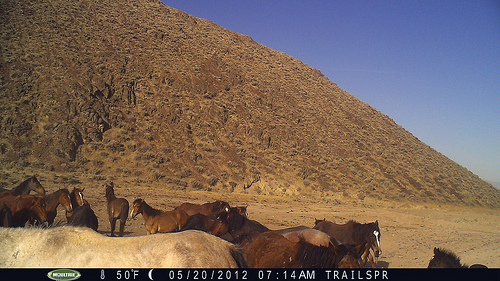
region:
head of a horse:
[362, 215, 400, 262]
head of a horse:
[222, 204, 257, 243]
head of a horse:
[125, 186, 159, 224]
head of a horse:
[100, 176, 127, 203]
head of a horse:
[72, 168, 94, 214]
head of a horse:
[51, 189, 82, 221]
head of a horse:
[30, 180, 53, 195]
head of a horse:
[32, 189, 63, 221]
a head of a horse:
[72, 176, 97, 206]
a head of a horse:
[25, 167, 48, 197]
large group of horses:
[27, 167, 410, 266]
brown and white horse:
[316, 204, 393, 262]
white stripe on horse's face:
[365, 232, 382, 256]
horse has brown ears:
[360, 211, 379, 233]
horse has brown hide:
[316, 211, 377, 253]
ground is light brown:
[322, 204, 447, 274]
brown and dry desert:
[403, 211, 463, 258]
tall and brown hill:
[3, 11, 395, 202]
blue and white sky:
[403, 72, 499, 188]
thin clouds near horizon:
[425, 74, 497, 186]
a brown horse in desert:
[102, 180, 128, 235]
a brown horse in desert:
[66, 185, 89, 222]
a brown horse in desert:
[32, 184, 74, 226]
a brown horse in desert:
[0, 189, 46, 227]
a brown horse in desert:
[9, 174, 45, 196]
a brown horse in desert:
[129, 196, 186, 233]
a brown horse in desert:
[175, 197, 230, 214]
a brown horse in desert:
[183, 205, 248, 234]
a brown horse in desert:
[207, 205, 267, 242]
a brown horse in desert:
[241, 227, 364, 267]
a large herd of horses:
[7, 168, 459, 264]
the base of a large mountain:
[10, 5, 474, 199]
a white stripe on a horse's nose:
[367, 223, 387, 256]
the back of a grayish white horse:
[7, 230, 226, 264]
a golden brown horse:
[122, 200, 192, 230]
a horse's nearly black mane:
[283, 235, 348, 268]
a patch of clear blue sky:
[237, 10, 497, 172]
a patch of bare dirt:
[309, 202, 484, 269]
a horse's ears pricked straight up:
[423, 243, 445, 263]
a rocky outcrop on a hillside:
[51, 64, 131, 166]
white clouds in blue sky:
[360, 9, 408, 37]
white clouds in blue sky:
[450, 11, 498, 65]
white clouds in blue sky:
[355, 12, 405, 62]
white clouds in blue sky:
[387, 29, 454, 73]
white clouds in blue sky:
[422, 86, 459, 128]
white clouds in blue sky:
[342, 19, 382, 53]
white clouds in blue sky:
[378, 58, 442, 106]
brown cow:
[114, 189, 268, 239]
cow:
[304, 203, 404, 264]